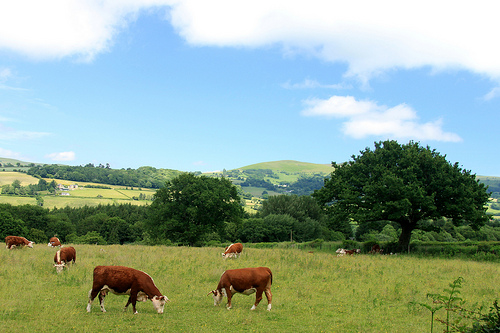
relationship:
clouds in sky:
[7, 1, 498, 147] [254, 57, 395, 79]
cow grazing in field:
[84, 265, 170, 316] [289, 254, 498, 326]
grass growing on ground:
[0, 240, 499, 333] [1, 157, 484, 331]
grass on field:
[289, 247, 441, 328] [98, 188, 462, 324]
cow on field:
[190, 266, 292, 313] [11, 228, 493, 329]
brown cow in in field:
[4, 228, 35, 253] [3, 224, 53, 320]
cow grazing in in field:
[5, 221, 36, 251] [3, 224, 53, 320]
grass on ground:
[0, 240, 499, 333] [1, 157, 484, 331]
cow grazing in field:
[87, 265, 159, 314] [302, 273, 422, 316]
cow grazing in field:
[45, 234, 65, 249] [1, 239, 498, 331]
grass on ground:
[0, 240, 499, 333] [5, 240, 465, 330]